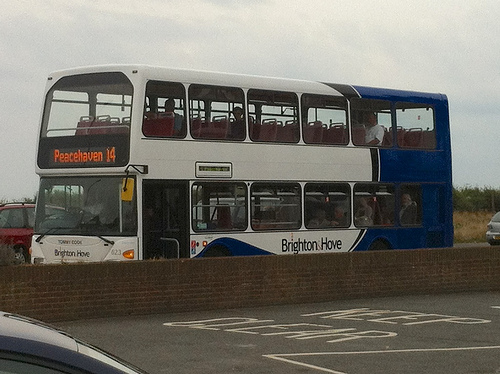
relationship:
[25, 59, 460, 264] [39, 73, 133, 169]
bus has window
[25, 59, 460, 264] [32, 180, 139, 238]
bus has windshield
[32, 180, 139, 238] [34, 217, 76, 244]
windshield has wiper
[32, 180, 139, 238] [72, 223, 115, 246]
windshield has wiper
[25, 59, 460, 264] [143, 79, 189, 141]
bus has window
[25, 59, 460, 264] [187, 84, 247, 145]
bus has window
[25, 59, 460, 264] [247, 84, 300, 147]
bus has window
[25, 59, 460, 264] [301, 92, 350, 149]
bus has window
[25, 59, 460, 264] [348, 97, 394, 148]
bus has window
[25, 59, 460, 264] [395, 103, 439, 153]
bus has window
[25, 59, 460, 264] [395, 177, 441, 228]
bus has window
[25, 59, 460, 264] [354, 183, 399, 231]
bus has window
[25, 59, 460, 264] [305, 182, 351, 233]
bus has window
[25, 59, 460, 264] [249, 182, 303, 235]
bus has window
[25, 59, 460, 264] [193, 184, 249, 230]
bus has window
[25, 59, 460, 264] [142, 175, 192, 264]
bus has door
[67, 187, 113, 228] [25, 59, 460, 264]
man drives bus